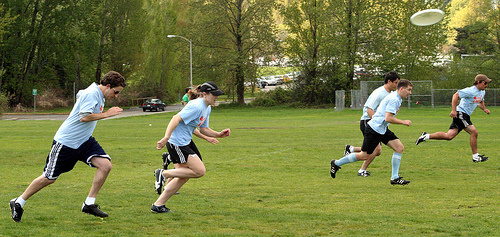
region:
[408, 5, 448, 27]
white frisbee flying through air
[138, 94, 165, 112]
car moving on street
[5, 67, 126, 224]
man wearing glasses on head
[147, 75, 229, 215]
woman wearing black hat on head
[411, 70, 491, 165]
man wearing hat and glasses on head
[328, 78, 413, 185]
man wearing blue-ish knee high socks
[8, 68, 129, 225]
man wearing black and white gym shorts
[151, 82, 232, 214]
woman wearing black and white gym shorts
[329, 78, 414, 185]
man running on green grass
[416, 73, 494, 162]
man wearing black and white sports shoes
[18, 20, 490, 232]
People are running around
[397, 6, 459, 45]
White frisbee in the air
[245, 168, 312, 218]
Green grass is short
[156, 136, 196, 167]
Pants are black and white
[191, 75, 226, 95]
Cap is black and white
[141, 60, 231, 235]
This is a female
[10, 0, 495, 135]
There are trees in the background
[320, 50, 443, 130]
This is a fence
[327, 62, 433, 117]
Fence is silver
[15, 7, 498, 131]
The sky is sunny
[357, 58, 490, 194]
three men running in a field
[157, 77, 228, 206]
a girl running in a field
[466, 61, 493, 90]
a man wearing a hat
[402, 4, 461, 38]
a white frisbee in the air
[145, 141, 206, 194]
a girl with one foot raised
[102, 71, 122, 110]
a man wearing sunglasses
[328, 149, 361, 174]
a man wearing blue and white socks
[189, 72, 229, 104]
a woman wearing a black and grey hat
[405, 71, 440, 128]
chain link fence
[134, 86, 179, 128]
a car on a street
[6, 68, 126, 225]
An athlete running on a field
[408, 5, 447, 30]
A white frisbee in the air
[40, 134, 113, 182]
A pair of black shorts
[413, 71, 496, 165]
A man in a hat running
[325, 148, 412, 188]
An athlete wearing blue socks and black shoes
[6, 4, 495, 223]
A team playing a frisbee game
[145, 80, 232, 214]
A female athlete running on a field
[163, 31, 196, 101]
A street light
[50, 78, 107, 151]
A light blue t-shirt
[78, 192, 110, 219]
A black shoe and white sock